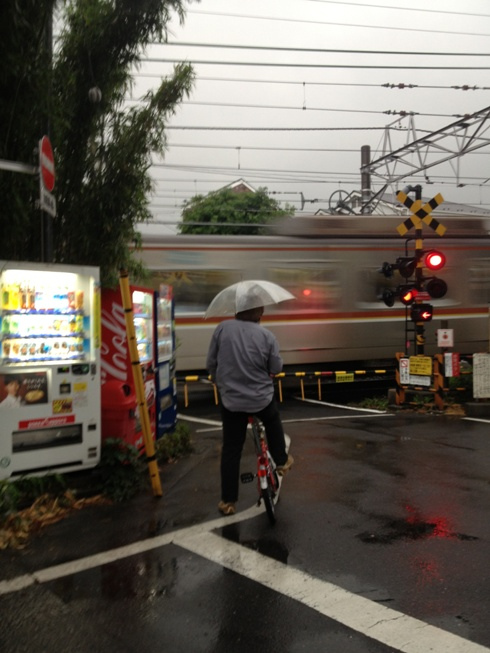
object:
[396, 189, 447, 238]
sign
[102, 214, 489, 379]
train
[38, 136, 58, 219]
sign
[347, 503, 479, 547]
puddle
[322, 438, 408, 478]
puddle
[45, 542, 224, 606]
puddle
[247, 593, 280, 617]
ground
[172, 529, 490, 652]
line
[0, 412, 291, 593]
line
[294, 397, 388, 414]
line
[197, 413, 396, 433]
line